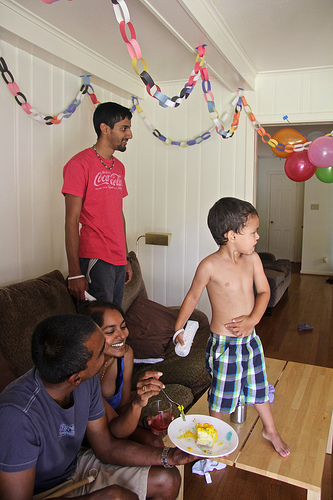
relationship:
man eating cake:
[8, 325, 114, 492] [190, 421, 220, 450]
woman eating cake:
[91, 308, 165, 422] [190, 421, 220, 450]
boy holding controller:
[171, 193, 290, 461] [164, 310, 207, 362]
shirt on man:
[58, 141, 129, 267] [58, 99, 135, 312]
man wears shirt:
[61, 101, 133, 313] [61, 143, 130, 267]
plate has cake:
[167, 414, 238, 460] [192, 420, 221, 448]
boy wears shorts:
[171, 193, 290, 461] [202, 328, 270, 413]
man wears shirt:
[0, 313, 201, 499] [0, 368, 107, 494]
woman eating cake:
[89, 302, 165, 436] [195, 421, 218, 447]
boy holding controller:
[172, 196, 290, 457] [174, 317, 203, 355]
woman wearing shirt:
[89, 302, 165, 436] [2, 366, 107, 488]